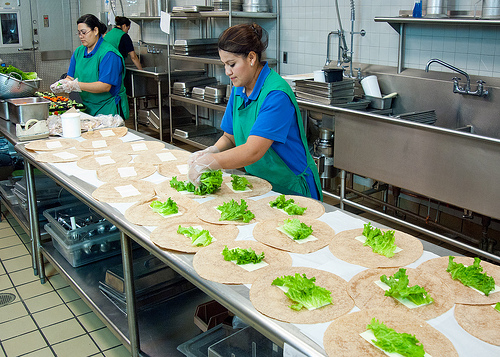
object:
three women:
[50, 13, 323, 200]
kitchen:
[0, 0, 497, 355]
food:
[192, 237, 294, 284]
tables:
[16, 127, 498, 357]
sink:
[285, 59, 499, 220]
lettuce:
[221, 246, 263, 265]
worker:
[187, 23, 324, 201]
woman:
[103, 16, 141, 73]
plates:
[126, 60, 149, 71]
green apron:
[102, 27, 125, 53]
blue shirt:
[221, 60, 321, 199]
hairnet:
[217, 20, 270, 54]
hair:
[217, 22, 263, 55]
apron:
[232, 68, 322, 198]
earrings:
[249, 60, 254, 67]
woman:
[49, 14, 129, 126]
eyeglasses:
[78, 28, 91, 35]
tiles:
[24, 289, 66, 313]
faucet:
[424, 59, 490, 97]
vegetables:
[1, 63, 38, 79]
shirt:
[104, 26, 134, 58]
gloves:
[50, 78, 83, 95]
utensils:
[68, 216, 78, 245]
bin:
[43, 203, 141, 268]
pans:
[175, 37, 218, 46]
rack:
[168, 1, 282, 161]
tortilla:
[192, 237, 295, 285]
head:
[115, 16, 131, 33]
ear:
[92, 27, 100, 37]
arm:
[58, 51, 123, 93]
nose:
[76, 35, 85, 40]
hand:
[55, 77, 78, 93]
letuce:
[168, 169, 225, 195]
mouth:
[79, 38, 87, 43]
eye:
[82, 30, 88, 35]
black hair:
[116, 16, 132, 25]